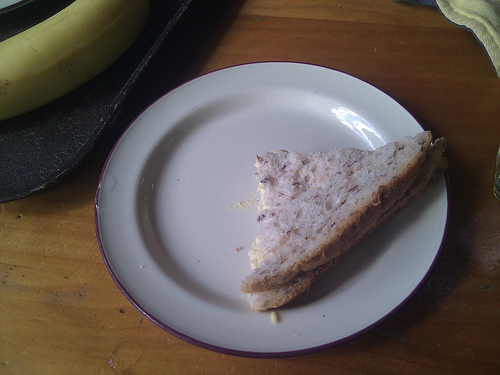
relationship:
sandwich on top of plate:
[248, 131, 447, 310] [92, 59, 449, 360]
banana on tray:
[3, 3, 158, 122] [1, 2, 192, 205]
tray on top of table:
[1, 2, 192, 205] [2, 1, 498, 374]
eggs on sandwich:
[252, 177, 271, 271] [248, 131, 447, 310]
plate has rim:
[92, 59, 449, 360] [252, 48, 364, 93]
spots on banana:
[4, 75, 45, 98] [3, 3, 158, 122]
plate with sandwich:
[92, 59, 449, 360] [248, 131, 447, 310]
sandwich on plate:
[248, 131, 447, 310] [92, 59, 449, 360]